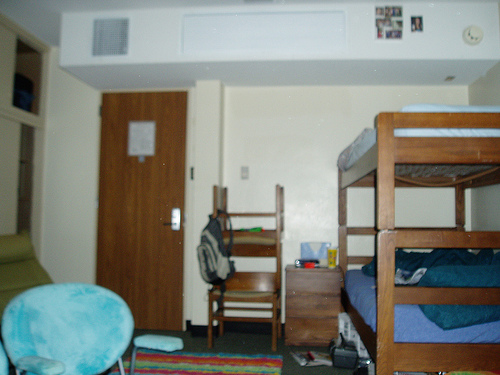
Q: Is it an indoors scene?
A: Yes, it is indoors.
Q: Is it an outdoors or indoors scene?
A: It is indoors.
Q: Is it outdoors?
A: No, it is indoors.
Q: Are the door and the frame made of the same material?
A: Yes, both the door and the frame are made of wood.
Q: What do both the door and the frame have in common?
A: The material, both the door and the frame are wooden.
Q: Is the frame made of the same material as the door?
A: Yes, both the frame and the door are made of wood.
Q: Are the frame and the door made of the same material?
A: Yes, both the frame and the door are made of wood.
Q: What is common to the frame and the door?
A: The material, both the frame and the door are wooden.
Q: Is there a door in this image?
A: Yes, there is a door.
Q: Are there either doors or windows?
A: Yes, there is a door.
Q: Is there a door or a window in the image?
A: Yes, there is a door.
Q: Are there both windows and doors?
A: No, there is a door but no windows.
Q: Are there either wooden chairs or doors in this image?
A: Yes, there is a wood door.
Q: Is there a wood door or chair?
A: Yes, there is a wood door.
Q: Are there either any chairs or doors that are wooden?
A: Yes, the door is wooden.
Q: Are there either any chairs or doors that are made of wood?
A: Yes, the door is made of wood.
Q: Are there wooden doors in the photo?
A: Yes, there is a wood door.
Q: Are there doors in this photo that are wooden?
A: Yes, there is a wood door.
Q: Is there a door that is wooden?
A: Yes, there is a door that is wooden.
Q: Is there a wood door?
A: Yes, there is a door that is made of wood.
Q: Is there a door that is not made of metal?
A: Yes, there is a door that is made of wood.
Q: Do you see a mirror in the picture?
A: No, there are no mirrors.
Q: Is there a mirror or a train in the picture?
A: No, there are no mirrors or trains.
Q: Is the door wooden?
A: Yes, the door is wooden.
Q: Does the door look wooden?
A: Yes, the door is wooden.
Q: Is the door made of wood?
A: Yes, the door is made of wood.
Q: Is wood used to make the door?
A: Yes, the door is made of wood.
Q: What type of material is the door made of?
A: The door is made of wood.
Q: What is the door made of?
A: The door is made of wood.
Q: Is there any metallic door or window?
A: No, there is a door but it is wooden.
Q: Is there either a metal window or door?
A: No, there is a door but it is wooden.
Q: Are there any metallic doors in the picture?
A: No, there is a door but it is wooden.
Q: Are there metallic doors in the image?
A: No, there is a door but it is wooden.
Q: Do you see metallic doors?
A: No, there is a door but it is wooden.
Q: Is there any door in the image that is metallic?
A: No, there is a door but it is wooden.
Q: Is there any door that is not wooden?
A: No, there is a door but it is wooden.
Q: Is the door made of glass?
A: No, the door is made of wood.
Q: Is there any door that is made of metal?
A: No, there is a door but it is made of wood.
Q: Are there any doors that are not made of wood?
A: No, there is a door but it is made of wood.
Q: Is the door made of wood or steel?
A: The door is made of wood.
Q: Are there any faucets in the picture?
A: No, there are no faucets.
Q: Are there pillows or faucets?
A: No, there are no faucets or pillows.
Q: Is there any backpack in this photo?
A: Yes, there is a backpack.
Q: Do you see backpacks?
A: Yes, there is a backpack.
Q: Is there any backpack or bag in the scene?
A: Yes, there is a backpack.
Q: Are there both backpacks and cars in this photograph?
A: No, there is a backpack but no cars.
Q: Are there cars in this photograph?
A: No, there are no cars.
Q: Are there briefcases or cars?
A: No, there are no cars or briefcases.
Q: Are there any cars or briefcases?
A: No, there are no cars or briefcases.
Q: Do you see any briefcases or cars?
A: No, there are no cars or briefcases.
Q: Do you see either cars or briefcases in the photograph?
A: No, there are no cars or briefcases.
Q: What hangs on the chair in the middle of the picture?
A: The backpack hangs on the chair.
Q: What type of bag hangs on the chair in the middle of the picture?
A: The bag is a backpack.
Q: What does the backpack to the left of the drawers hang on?
A: The backpack hangs on the chair.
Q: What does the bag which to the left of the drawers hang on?
A: The backpack hangs on the chair.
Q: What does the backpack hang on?
A: The backpack hangs on the chair.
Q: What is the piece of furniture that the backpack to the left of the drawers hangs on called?
A: The piece of furniture is a chair.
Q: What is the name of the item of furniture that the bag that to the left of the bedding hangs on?
A: The piece of furniture is a chair.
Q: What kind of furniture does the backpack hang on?
A: The backpack hangs on the chair.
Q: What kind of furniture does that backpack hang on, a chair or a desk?
A: The backpack hangs on a chair.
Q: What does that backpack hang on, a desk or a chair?
A: The backpack hangs on a chair.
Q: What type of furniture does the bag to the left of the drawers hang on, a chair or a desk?
A: The backpack hangs on a chair.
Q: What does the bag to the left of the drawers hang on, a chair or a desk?
A: The backpack hangs on a chair.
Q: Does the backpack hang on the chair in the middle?
A: Yes, the backpack hangs on the chair.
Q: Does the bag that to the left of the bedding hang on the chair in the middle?
A: Yes, the backpack hangs on the chair.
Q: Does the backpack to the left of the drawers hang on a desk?
A: No, the backpack hangs on the chair.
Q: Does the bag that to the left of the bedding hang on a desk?
A: No, the backpack hangs on the chair.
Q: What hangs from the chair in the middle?
A: The backpack hangs from the chair.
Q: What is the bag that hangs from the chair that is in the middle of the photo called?
A: The bag is a backpack.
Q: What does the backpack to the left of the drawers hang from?
A: The backpack hangs from the chair.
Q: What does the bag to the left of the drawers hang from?
A: The backpack hangs from the chair.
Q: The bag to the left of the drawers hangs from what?
A: The backpack hangs from the chair.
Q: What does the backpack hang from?
A: The backpack hangs from the chair.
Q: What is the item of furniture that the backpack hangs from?
A: The piece of furniture is a chair.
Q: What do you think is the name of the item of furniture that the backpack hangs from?
A: The piece of furniture is a chair.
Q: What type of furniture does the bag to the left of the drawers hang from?
A: The backpack hangs from the chair.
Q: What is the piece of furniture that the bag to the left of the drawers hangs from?
A: The piece of furniture is a chair.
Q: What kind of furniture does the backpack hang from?
A: The backpack hangs from the chair.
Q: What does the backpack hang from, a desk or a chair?
A: The backpack hangs from a chair.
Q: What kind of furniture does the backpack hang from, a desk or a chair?
A: The backpack hangs from a chair.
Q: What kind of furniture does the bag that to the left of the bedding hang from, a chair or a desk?
A: The backpack hangs from a chair.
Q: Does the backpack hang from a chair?
A: Yes, the backpack hangs from a chair.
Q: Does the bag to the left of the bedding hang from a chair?
A: Yes, the backpack hangs from a chair.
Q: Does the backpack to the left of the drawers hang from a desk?
A: No, the backpack hangs from a chair.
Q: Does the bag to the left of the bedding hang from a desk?
A: No, the backpack hangs from a chair.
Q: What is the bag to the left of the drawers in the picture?
A: The bag is a backpack.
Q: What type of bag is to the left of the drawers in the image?
A: The bag is a backpack.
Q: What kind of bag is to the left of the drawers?
A: The bag is a backpack.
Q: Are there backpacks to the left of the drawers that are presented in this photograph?
A: Yes, there is a backpack to the left of the drawers.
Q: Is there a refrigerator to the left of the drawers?
A: No, there is a backpack to the left of the drawers.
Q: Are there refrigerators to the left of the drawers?
A: No, there is a backpack to the left of the drawers.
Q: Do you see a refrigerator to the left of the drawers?
A: No, there is a backpack to the left of the drawers.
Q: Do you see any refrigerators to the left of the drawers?
A: No, there is a backpack to the left of the drawers.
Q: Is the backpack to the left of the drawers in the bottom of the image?
A: Yes, the backpack is to the left of the drawers.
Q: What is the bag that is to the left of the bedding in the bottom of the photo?
A: The bag is a backpack.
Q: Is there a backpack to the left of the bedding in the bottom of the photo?
A: Yes, there is a backpack to the left of the bedding.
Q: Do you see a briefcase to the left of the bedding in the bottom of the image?
A: No, there is a backpack to the left of the bedding.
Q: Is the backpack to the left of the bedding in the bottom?
A: Yes, the backpack is to the left of the bedding.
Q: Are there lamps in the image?
A: No, there are no lamps.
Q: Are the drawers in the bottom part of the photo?
A: Yes, the drawers are in the bottom of the image.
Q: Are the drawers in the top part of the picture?
A: No, the drawers are in the bottom of the image.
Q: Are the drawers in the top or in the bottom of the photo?
A: The drawers are in the bottom of the image.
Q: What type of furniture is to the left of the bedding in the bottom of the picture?
A: The pieces of furniture are drawers.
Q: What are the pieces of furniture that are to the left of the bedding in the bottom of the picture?
A: The pieces of furniture are drawers.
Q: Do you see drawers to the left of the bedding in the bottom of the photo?
A: Yes, there are drawers to the left of the bedding.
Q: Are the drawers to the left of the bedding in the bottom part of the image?
A: Yes, the drawers are to the left of the bedding.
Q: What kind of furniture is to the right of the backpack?
A: The pieces of furniture are drawers.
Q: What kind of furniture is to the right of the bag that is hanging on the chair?
A: The pieces of furniture are drawers.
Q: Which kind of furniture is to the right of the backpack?
A: The pieces of furniture are drawers.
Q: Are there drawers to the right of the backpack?
A: Yes, there are drawers to the right of the backpack.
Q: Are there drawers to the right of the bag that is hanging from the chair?
A: Yes, there are drawers to the right of the backpack.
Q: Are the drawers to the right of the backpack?
A: Yes, the drawers are to the right of the backpack.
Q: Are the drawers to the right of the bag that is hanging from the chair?
A: Yes, the drawers are to the right of the backpack.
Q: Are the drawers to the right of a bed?
A: No, the drawers are to the right of the backpack.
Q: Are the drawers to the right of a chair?
A: Yes, the drawers are to the right of a chair.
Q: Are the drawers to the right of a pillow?
A: No, the drawers are to the right of a chair.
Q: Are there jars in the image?
A: No, there are no jars.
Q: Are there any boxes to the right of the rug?
A: Yes, there is a box to the right of the rug.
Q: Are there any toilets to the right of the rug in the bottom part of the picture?
A: No, there is a box to the right of the rug.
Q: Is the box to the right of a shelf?
A: No, the box is to the right of the rug.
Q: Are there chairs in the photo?
A: Yes, there is a chair.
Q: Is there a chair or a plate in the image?
A: Yes, there is a chair.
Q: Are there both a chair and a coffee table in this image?
A: No, there is a chair but no coffee tables.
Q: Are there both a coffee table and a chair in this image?
A: No, there is a chair but no coffee tables.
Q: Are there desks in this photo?
A: No, there are no desks.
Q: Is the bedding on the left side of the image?
A: No, the bedding is on the right of the image.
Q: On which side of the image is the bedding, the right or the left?
A: The bedding is on the right of the image.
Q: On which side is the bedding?
A: The bedding is on the right of the image.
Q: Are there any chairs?
A: Yes, there is a chair.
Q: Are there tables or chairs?
A: Yes, there is a chair.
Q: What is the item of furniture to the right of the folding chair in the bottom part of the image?
A: The piece of furniture is a chair.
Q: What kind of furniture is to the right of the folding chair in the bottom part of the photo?
A: The piece of furniture is a chair.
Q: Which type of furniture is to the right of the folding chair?
A: The piece of furniture is a chair.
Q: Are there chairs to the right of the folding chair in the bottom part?
A: Yes, there is a chair to the right of the folding chair.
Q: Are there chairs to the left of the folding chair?
A: No, the chair is to the right of the folding chair.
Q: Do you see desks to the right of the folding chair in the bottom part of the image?
A: No, there is a chair to the right of the folding chair.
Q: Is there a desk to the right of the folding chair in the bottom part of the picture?
A: No, there is a chair to the right of the folding chair.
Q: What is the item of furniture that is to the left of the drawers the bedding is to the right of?
A: The piece of furniture is a chair.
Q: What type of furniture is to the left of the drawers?
A: The piece of furniture is a chair.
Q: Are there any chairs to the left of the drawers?
A: Yes, there is a chair to the left of the drawers.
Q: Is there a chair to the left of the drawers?
A: Yes, there is a chair to the left of the drawers.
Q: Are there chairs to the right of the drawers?
A: No, the chair is to the left of the drawers.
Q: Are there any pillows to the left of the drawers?
A: No, there is a chair to the left of the drawers.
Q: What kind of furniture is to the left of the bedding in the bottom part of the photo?
A: The piece of furniture is a chair.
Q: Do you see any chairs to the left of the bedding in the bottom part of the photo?
A: Yes, there is a chair to the left of the bedding.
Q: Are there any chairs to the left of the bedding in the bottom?
A: Yes, there is a chair to the left of the bedding.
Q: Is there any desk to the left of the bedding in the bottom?
A: No, there is a chair to the left of the bedding.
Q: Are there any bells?
A: No, there are no bells.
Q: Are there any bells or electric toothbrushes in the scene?
A: No, there are no bells or electric toothbrushes.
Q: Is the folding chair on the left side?
A: Yes, the folding chair is on the left of the image.